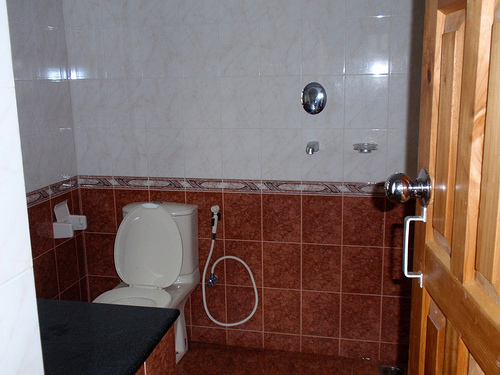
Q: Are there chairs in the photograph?
A: No, there are no chairs.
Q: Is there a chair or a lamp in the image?
A: No, there are no chairs or lamps.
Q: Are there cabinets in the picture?
A: No, there are no cabinets.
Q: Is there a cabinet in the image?
A: No, there are no cabinets.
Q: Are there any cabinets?
A: No, there are no cabinets.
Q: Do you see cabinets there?
A: No, there are no cabinets.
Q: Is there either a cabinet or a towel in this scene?
A: No, there are no cabinets or towels.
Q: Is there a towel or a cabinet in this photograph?
A: No, there are no cabinets or towels.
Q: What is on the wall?
A: The tiles are on the wall.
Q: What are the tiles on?
A: The tiles are on the wall.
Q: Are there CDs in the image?
A: No, there are no cds.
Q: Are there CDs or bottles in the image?
A: No, there are no CDs or bottles.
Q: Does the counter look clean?
A: Yes, the counter is clean.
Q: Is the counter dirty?
A: No, the counter is clean.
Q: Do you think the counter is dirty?
A: No, the counter is clean.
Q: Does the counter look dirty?
A: No, the counter is clean.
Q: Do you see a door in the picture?
A: Yes, there is a door.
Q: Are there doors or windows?
A: Yes, there is a door.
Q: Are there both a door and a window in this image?
A: No, there is a door but no windows.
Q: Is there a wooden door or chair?
A: Yes, there is a wood door.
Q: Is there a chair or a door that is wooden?
A: Yes, the door is wooden.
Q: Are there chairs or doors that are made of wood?
A: Yes, the door is made of wood.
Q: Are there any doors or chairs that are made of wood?
A: Yes, the door is made of wood.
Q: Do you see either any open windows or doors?
A: Yes, there is an open door.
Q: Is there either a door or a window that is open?
A: Yes, the door is open.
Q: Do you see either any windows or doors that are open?
A: Yes, the door is open.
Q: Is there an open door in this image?
A: Yes, there is an open door.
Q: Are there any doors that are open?
A: Yes, there is a door that is open.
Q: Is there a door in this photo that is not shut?
A: Yes, there is a open door.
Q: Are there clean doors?
A: Yes, there is a clean door.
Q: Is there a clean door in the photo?
A: Yes, there is a clean door.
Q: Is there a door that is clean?
A: Yes, there is a door that is clean.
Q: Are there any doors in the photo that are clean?
A: Yes, there is a door that is clean.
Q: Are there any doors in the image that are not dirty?
A: Yes, there is a clean door.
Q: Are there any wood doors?
A: Yes, there is a wood door.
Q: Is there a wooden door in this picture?
A: Yes, there is a wood door.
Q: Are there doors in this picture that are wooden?
A: Yes, there is a door that is wooden.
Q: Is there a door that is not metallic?
A: Yes, there is a wooden door.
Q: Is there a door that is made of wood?
A: Yes, there is a door that is made of wood.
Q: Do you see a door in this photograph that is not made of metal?
A: Yes, there is a door that is made of wood.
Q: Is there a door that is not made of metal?
A: Yes, there is a door that is made of wood.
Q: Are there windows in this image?
A: No, there are no windows.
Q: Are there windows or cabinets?
A: No, there are no windows or cabinets.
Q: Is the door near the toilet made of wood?
A: Yes, the door is made of wood.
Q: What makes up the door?
A: The door is made of wood.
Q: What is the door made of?
A: The door is made of wood.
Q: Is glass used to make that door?
A: No, the door is made of wood.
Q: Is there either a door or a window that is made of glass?
A: No, there is a door but it is made of wood.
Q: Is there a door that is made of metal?
A: No, there is a door but it is made of wood.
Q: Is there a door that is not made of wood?
A: No, there is a door but it is made of wood.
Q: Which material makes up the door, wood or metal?
A: The door is made of wood.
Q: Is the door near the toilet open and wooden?
A: Yes, the door is open and wooden.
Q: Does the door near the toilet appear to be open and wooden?
A: Yes, the door is open and wooden.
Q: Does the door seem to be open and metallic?
A: No, the door is open but wooden.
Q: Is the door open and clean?
A: Yes, the door is open and clean.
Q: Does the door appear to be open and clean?
A: Yes, the door is open and clean.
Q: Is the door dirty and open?
A: No, the door is open but clean.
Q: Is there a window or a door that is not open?
A: No, there is a door but it is open.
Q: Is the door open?
A: Yes, the door is open.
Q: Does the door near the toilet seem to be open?
A: Yes, the door is open.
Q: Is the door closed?
A: No, the door is open.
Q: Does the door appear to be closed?
A: No, the door is open.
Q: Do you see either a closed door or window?
A: No, there is a door but it is open.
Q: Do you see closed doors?
A: No, there is a door but it is open.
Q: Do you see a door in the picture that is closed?
A: No, there is a door but it is open.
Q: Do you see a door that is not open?
A: No, there is a door but it is open.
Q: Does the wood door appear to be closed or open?
A: The door is open.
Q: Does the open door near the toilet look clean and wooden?
A: Yes, the door is clean and wooden.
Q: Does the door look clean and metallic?
A: No, the door is clean but wooden.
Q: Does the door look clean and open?
A: Yes, the door is clean and open.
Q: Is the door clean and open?
A: Yes, the door is clean and open.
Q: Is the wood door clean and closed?
A: No, the door is clean but open.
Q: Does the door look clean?
A: Yes, the door is clean.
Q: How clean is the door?
A: The door is clean.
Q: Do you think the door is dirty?
A: No, the door is clean.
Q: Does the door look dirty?
A: No, the door is clean.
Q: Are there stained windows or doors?
A: No, there is a door but it is clean.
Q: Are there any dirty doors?
A: No, there is a door but it is clean.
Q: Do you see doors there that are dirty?
A: No, there is a door but it is clean.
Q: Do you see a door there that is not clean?
A: No, there is a door but it is clean.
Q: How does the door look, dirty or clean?
A: The door is clean.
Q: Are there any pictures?
A: No, there are no pictures.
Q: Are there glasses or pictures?
A: No, there are no pictures or glasses.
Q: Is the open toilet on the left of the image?
A: Yes, the toilet is on the left of the image.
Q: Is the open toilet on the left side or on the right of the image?
A: The toilet is on the left of the image.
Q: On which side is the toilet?
A: The toilet is on the left of the image.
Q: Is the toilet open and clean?
A: Yes, the toilet is open and clean.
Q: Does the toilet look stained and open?
A: No, the toilet is open but clean.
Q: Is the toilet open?
A: Yes, the toilet is open.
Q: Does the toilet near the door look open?
A: Yes, the toilet is open.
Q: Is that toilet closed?
A: No, the toilet is open.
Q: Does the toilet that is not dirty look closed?
A: No, the toilet is open.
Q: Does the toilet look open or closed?
A: The toilet is open.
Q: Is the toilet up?
A: Yes, the toilet is up.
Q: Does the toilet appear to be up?
A: Yes, the toilet is up.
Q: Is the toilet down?
A: No, the toilet is up.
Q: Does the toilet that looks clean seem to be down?
A: No, the toilet is up.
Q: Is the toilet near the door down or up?
A: The toilet is up.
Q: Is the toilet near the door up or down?
A: The toilet is up.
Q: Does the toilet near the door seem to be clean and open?
A: Yes, the toilet is clean and open.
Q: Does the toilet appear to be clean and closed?
A: No, the toilet is clean but open.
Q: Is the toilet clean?
A: Yes, the toilet is clean.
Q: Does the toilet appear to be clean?
A: Yes, the toilet is clean.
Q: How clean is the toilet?
A: The toilet is clean.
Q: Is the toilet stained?
A: No, the toilet is clean.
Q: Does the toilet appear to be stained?
A: No, the toilet is clean.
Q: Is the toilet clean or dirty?
A: The toilet is clean.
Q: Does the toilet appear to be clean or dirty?
A: The toilet is clean.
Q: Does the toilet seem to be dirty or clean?
A: The toilet is clean.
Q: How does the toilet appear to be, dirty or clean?
A: The toilet is clean.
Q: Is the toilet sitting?
A: Yes, the toilet is sitting.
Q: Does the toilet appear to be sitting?
A: Yes, the toilet is sitting.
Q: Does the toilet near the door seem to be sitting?
A: Yes, the toilet is sitting.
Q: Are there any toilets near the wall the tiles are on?
A: Yes, there is a toilet near the wall.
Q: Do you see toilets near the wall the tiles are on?
A: Yes, there is a toilet near the wall.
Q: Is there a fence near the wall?
A: No, there is a toilet near the wall.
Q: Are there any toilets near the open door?
A: Yes, there is a toilet near the door.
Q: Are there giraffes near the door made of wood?
A: No, there is a toilet near the door.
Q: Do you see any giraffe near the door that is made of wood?
A: No, there is a toilet near the door.